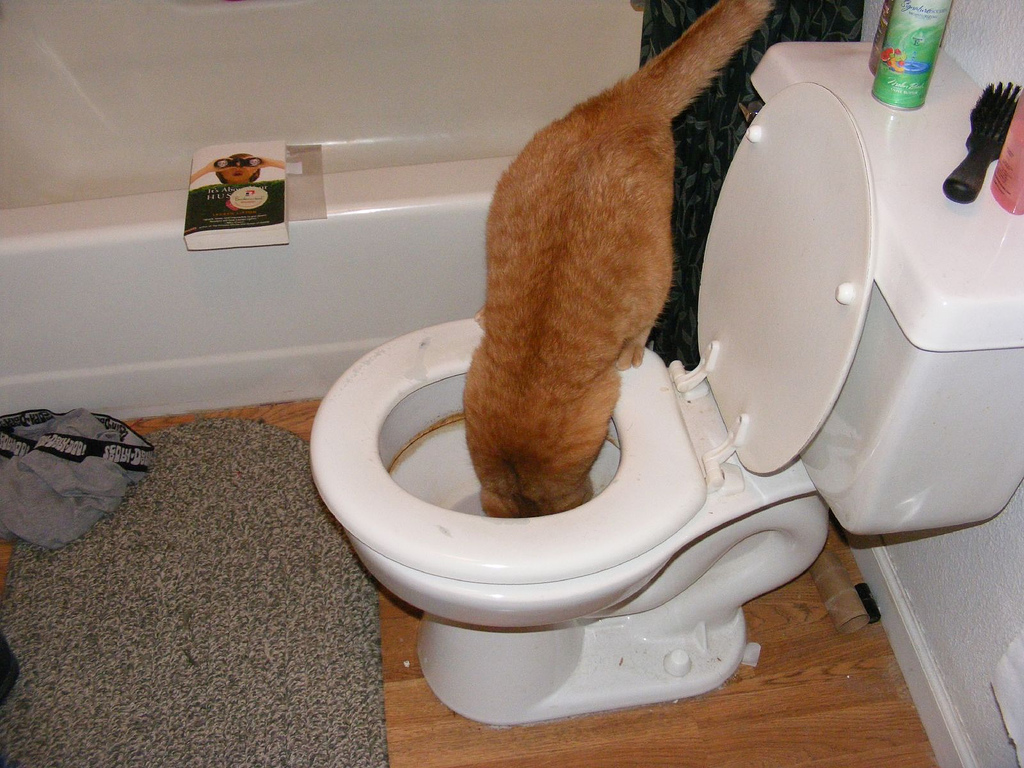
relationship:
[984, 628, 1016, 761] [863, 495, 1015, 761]
paper on wall